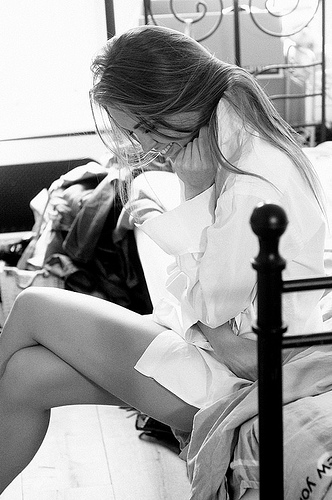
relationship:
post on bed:
[249, 200, 289, 497] [249, 199, 330, 499]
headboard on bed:
[84, 0, 328, 132] [99, 0, 330, 494]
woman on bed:
[1, 26, 325, 497] [268, 229, 288, 452]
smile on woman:
[149, 136, 185, 169] [1, 26, 325, 497]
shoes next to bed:
[122, 399, 195, 455] [98, 3, 329, 449]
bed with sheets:
[120, 13, 321, 255] [122, 140, 330, 354]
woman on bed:
[1, 26, 325, 499] [301, 140, 330, 186]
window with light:
[0, 6, 52, 130] [0, 6, 138, 143]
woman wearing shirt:
[1, 26, 325, 497] [132, 93, 327, 411]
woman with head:
[1, 26, 325, 497] [77, 17, 293, 198]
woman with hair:
[1, 26, 325, 497] [85, 25, 325, 200]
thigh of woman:
[19, 281, 195, 428] [1, 26, 325, 497]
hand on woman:
[204, 316, 260, 381] [1, 26, 325, 497]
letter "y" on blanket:
[302, 473, 317, 493] [179, 343, 331, 499]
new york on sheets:
[300, 453, 330, 498] [179, 345, 331, 499]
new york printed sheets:
[300, 453, 330, 498] [181, 397, 330, 496]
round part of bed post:
[247, 202, 288, 270] [248, 199, 286, 498]